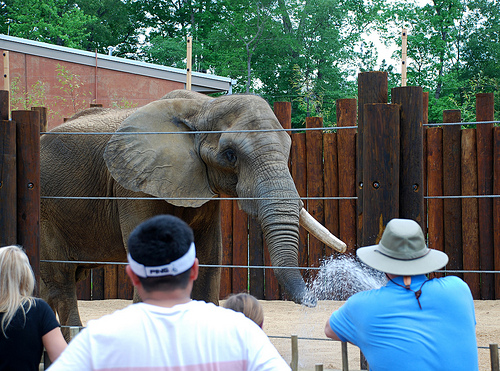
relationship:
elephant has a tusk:
[41, 91, 308, 303] [299, 206, 350, 255]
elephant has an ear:
[41, 91, 308, 303] [102, 98, 219, 209]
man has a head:
[43, 215, 290, 369] [126, 212, 200, 299]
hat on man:
[355, 217, 448, 277] [326, 215, 479, 369]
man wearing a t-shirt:
[326, 215, 479, 369] [327, 272, 481, 369]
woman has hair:
[0, 242, 68, 370] [1, 242, 35, 340]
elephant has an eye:
[41, 91, 308, 303] [223, 147, 234, 164]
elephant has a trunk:
[41, 91, 308, 303] [235, 174, 312, 300]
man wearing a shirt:
[43, 215, 290, 369] [43, 297, 293, 369]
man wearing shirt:
[326, 215, 479, 369] [327, 272, 481, 369]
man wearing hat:
[326, 215, 479, 369] [355, 217, 448, 277]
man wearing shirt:
[43, 215, 290, 369] [43, 297, 293, 369]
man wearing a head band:
[43, 215, 290, 369] [127, 241, 196, 278]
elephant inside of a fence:
[41, 91, 308, 303] [5, 69, 497, 301]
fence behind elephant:
[5, 69, 497, 301] [41, 91, 308, 303]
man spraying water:
[326, 215, 479, 369] [301, 251, 387, 307]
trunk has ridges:
[235, 174, 312, 300] [259, 207, 301, 258]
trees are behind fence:
[0, 1, 498, 126] [5, 69, 497, 301]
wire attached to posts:
[36, 127, 499, 277] [1, 71, 426, 299]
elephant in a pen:
[41, 91, 308, 303] [2, 71, 496, 366]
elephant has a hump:
[41, 91, 308, 303] [69, 86, 212, 121]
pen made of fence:
[2, 71, 496, 366] [5, 69, 497, 301]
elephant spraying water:
[41, 91, 308, 303] [301, 251, 387, 307]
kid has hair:
[223, 293, 262, 329] [222, 290, 262, 327]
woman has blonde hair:
[0, 242, 68, 370] [1, 242, 35, 340]